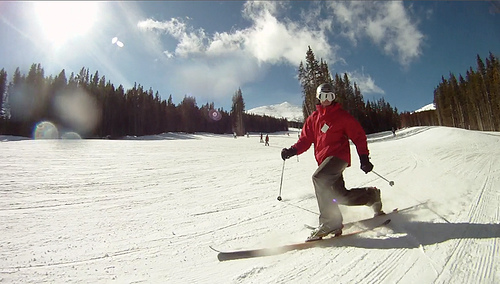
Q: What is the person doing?
A: Skiing.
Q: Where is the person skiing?
A: On a mountain.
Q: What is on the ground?
A: Snow.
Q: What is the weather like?
A: Sunny.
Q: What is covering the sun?
A: Clouds.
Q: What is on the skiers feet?
A: Skis.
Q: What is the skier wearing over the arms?
A: A coat.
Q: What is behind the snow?
A: Trees.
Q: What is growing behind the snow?
A: Trees.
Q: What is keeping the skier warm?
A: A coat.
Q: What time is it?
A: Afternoon.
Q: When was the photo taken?
A: During the daytime.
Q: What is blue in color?
A: The sky.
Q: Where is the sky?
A: Above the skier.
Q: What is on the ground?
A: Snow.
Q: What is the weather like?
A: Sunny.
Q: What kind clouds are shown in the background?
A: Stratus.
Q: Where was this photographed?
A: Mountain.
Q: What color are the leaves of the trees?
A: Green.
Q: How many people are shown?
A: Seven.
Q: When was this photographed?
A: Day time.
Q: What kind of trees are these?
A: Evergreen.